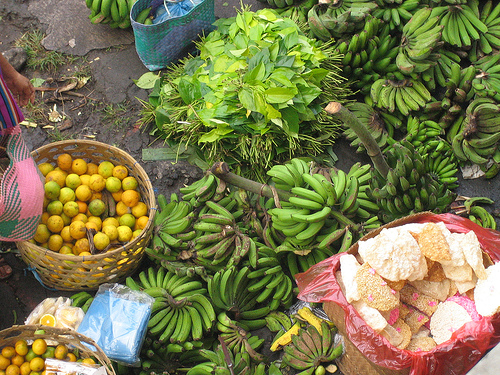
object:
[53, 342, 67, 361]
orange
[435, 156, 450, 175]
banana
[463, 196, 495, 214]
banana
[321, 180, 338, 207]
banana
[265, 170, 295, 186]
banana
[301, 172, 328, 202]
banana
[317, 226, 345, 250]
banana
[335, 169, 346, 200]
banana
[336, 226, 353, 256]
banana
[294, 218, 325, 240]
banana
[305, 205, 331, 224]
banana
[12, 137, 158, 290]
basket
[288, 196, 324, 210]
bananas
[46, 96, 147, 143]
dirt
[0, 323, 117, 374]
basket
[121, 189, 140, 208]
fruit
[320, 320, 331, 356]
banana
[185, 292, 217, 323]
banana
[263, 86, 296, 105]
leaves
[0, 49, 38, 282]
person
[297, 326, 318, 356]
banana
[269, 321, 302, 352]
banana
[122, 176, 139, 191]
fruit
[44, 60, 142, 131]
muddy ground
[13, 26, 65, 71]
grass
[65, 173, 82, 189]
fruit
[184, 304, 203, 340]
bananas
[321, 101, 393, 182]
branch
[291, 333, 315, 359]
bananas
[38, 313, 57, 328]
lemon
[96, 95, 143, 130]
grass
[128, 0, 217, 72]
bag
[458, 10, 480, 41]
bananas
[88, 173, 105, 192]
fruit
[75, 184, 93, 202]
fruit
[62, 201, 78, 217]
fruit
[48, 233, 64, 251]
fruit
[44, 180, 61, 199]
fruit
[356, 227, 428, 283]
bread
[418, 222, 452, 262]
bread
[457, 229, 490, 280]
bread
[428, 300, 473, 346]
bread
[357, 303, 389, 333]
bread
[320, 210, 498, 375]
basket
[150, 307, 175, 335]
bananas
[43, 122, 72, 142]
grass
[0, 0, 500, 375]
ground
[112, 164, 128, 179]
fruit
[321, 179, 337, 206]
bananas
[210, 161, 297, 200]
branch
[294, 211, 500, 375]
bag